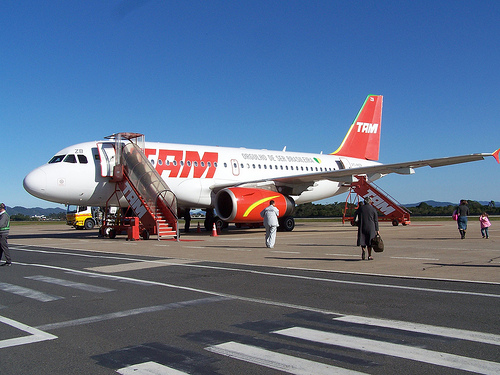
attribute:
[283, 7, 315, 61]
sky — blue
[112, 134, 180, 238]
stairs — airplane, loading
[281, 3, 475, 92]
sky — blue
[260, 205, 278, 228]
jacket — white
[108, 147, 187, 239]
stairs — red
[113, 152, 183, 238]
stairs — airplane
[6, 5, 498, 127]
sky — blue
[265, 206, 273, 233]
track suit — gray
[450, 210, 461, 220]
bag — brown, duffle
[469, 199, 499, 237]
girl — little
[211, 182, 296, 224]
propellor — red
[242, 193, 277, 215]
stripe — yellow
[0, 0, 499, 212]
sky — blue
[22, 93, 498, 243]
airplane — orange, white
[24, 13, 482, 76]
sky — blue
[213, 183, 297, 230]
booster — red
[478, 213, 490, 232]
jacket — pink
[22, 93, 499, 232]
plane — red, white, orange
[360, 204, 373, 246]
coat — black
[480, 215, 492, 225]
coat — pink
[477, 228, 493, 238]
jeans — blue